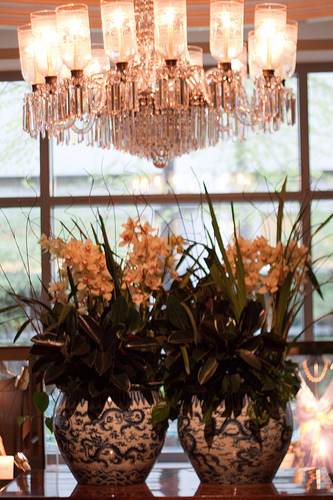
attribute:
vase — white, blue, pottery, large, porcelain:
[53, 384, 167, 486]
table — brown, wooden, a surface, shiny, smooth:
[2, 459, 331, 499]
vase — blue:
[178, 390, 292, 481]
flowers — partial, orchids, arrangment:
[7, 171, 179, 408]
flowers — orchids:
[166, 183, 313, 410]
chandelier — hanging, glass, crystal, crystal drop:
[16, 0, 299, 168]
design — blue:
[59, 402, 162, 481]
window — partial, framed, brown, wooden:
[1, 68, 328, 439]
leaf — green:
[79, 318, 108, 351]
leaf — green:
[33, 332, 63, 346]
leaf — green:
[89, 376, 109, 397]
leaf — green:
[127, 340, 157, 353]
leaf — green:
[45, 362, 66, 381]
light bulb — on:
[109, 8, 127, 41]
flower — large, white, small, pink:
[39, 233, 111, 306]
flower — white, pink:
[119, 215, 177, 304]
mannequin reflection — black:
[288, 349, 332, 472]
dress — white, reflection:
[293, 372, 332, 469]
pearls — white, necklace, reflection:
[300, 358, 328, 381]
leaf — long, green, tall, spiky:
[92, 208, 133, 312]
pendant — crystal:
[94, 116, 108, 149]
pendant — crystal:
[110, 115, 124, 143]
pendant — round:
[197, 111, 211, 147]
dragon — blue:
[79, 405, 145, 430]